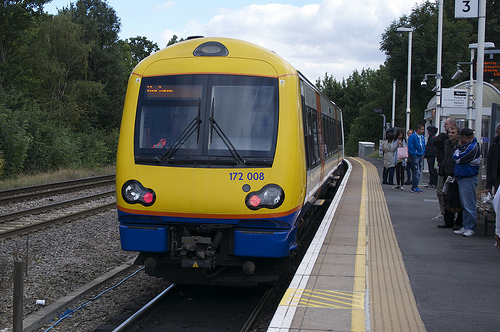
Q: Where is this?
A: This is at the station.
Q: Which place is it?
A: It is a station.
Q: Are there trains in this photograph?
A: Yes, there is a train.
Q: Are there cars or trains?
A: Yes, there is a train.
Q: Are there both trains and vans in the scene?
A: No, there is a train but no vans.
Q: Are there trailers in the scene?
A: No, there are no trailers.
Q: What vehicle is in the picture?
A: The vehicle is a train.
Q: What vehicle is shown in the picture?
A: The vehicle is a train.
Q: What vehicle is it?
A: The vehicle is a train.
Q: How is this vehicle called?
A: This is a train.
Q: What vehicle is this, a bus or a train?
A: This is a train.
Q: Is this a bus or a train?
A: This is a train.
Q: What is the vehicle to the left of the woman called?
A: The vehicle is a train.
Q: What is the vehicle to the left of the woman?
A: The vehicle is a train.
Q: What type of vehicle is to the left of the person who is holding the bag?
A: The vehicle is a train.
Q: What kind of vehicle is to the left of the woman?
A: The vehicle is a train.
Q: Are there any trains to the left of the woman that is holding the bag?
A: Yes, there is a train to the left of the woman.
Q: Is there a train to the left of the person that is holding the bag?
A: Yes, there is a train to the left of the woman.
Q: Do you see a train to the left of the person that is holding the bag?
A: Yes, there is a train to the left of the woman.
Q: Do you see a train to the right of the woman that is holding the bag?
A: No, the train is to the left of the woman.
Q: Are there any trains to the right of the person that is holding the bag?
A: No, the train is to the left of the woman.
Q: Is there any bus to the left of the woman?
A: No, there is a train to the left of the woman.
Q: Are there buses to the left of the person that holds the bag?
A: No, there is a train to the left of the woman.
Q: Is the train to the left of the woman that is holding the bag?
A: Yes, the train is to the left of the woman.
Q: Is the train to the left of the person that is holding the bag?
A: Yes, the train is to the left of the woman.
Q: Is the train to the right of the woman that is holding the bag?
A: No, the train is to the left of the woman.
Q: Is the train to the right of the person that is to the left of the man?
A: No, the train is to the left of the woman.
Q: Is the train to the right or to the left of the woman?
A: The train is to the left of the woman.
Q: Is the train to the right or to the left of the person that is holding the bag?
A: The train is to the left of the woman.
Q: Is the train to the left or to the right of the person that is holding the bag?
A: The train is to the left of the woman.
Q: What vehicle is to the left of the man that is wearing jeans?
A: The vehicle is a train.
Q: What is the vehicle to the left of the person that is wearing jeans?
A: The vehicle is a train.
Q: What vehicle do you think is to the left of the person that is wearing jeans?
A: The vehicle is a train.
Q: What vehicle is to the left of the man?
A: The vehicle is a train.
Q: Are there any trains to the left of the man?
A: Yes, there is a train to the left of the man.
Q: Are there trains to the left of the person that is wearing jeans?
A: Yes, there is a train to the left of the man.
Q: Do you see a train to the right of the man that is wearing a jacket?
A: No, the train is to the left of the man.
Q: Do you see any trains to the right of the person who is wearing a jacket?
A: No, the train is to the left of the man.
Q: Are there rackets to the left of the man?
A: No, there is a train to the left of the man.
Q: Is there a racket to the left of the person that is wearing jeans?
A: No, there is a train to the left of the man.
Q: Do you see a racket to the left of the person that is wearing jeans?
A: No, there is a train to the left of the man.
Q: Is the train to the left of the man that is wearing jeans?
A: Yes, the train is to the left of the man.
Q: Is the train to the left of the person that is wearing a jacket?
A: Yes, the train is to the left of the man.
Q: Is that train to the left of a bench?
A: No, the train is to the left of the man.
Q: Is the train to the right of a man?
A: No, the train is to the left of a man.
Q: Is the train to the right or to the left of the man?
A: The train is to the left of the man.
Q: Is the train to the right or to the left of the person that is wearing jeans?
A: The train is to the left of the man.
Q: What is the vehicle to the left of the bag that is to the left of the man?
A: The vehicle is a train.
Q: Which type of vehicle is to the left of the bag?
A: The vehicle is a train.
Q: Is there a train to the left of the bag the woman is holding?
A: Yes, there is a train to the left of the bag.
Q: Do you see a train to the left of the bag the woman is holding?
A: Yes, there is a train to the left of the bag.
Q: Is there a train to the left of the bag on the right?
A: Yes, there is a train to the left of the bag.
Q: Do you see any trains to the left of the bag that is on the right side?
A: Yes, there is a train to the left of the bag.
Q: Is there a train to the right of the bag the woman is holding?
A: No, the train is to the left of the bag.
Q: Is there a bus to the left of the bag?
A: No, there is a train to the left of the bag.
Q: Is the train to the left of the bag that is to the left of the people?
A: Yes, the train is to the left of the bag.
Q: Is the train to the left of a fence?
A: No, the train is to the left of the bag.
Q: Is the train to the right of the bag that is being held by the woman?
A: No, the train is to the left of the bag.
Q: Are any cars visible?
A: No, there are no cars.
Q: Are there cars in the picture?
A: No, there are no cars.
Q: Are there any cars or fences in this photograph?
A: No, there are no cars or fences.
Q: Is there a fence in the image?
A: No, there are no fences.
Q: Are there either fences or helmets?
A: No, there are no fences or helmets.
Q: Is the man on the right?
A: Yes, the man is on the right of the image.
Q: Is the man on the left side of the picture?
A: No, the man is on the right of the image.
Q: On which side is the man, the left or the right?
A: The man is on the right of the image.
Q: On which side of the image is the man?
A: The man is on the right of the image.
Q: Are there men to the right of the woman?
A: Yes, there is a man to the right of the woman.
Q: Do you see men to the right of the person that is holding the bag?
A: Yes, there is a man to the right of the woman.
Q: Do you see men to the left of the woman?
A: No, the man is to the right of the woman.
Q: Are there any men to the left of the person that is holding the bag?
A: No, the man is to the right of the woman.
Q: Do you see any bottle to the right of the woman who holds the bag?
A: No, there is a man to the right of the woman.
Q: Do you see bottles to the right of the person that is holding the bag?
A: No, there is a man to the right of the woman.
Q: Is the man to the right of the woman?
A: Yes, the man is to the right of the woman.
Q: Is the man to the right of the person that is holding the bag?
A: Yes, the man is to the right of the woman.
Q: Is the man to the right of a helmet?
A: No, the man is to the right of the woman.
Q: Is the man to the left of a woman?
A: No, the man is to the right of a woman.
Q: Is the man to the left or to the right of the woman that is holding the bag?
A: The man is to the right of the woman.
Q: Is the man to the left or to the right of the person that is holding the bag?
A: The man is to the right of the woman.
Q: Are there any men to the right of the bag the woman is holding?
A: Yes, there is a man to the right of the bag.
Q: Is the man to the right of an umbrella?
A: No, the man is to the right of the bag.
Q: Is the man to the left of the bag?
A: No, the man is to the right of the bag.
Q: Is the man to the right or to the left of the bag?
A: The man is to the right of the bag.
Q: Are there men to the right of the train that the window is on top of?
A: Yes, there is a man to the right of the train.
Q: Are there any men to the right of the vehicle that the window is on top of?
A: Yes, there is a man to the right of the train.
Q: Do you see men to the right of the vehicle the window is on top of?
A: Yes, there is a man to the right of the train.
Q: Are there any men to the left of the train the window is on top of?
A: No, the man is to the right of the train.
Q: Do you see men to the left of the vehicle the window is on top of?
A: No, the man is to the right of the train.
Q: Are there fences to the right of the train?
A: No, there is a man to the right of the train.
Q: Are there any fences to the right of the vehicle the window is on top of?
A: No, there is a man to the right of the train.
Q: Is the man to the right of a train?
A: Yes, the man is to the right of a train.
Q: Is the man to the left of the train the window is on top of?
A: No, the man is to the right of the train.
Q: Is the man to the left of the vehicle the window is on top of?
A: No, the man is to the right of the train.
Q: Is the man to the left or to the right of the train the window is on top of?
A: The man is to the right of the train.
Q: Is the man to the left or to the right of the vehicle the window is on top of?
A: The man is to the right of the train.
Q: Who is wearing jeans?
A: The man is wearing jeans.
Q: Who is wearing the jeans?
A: The man is wearing jeans.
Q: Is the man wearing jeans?
A: Yes, the man is wearing jeans.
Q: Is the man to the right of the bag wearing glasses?
A: No, the man is wearing jeans.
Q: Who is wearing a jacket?
A: The man is wearing a jacket.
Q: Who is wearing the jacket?
A: The man is wearing a jacket.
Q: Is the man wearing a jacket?
A: Yes, the man is wearing a jacket.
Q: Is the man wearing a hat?
A: No, the man is wearing a jacket.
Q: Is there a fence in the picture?
A: No, there are no fences.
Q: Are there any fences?
A: No, there are no fences.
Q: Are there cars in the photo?
A: No, there are no cars.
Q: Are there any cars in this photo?
A: No, there are no cars.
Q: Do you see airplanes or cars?
A: No, there are no cars or airplanes.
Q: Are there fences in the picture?
A: No, there are no fences.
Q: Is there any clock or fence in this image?
A: No, there are no fences or clocks.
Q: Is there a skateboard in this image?
A: No, there are no skateboards.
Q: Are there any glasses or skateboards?
A: No, there are no skateboards or glasses.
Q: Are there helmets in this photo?
A: No, there are no helmets.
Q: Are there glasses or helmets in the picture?
A: No, there are no helmets or glasses.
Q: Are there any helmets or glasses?
A: No, there are no helmets or glasses.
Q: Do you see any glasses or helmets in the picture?
A: No, there are no helmets or glasses.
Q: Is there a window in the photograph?
A: Yes, there is a window.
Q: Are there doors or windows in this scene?
A: Yes, there is a window.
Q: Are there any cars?
A: No, there are no cars.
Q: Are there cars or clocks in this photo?
A: No, there are no cars or clocks.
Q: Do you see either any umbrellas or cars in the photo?
A: No, there are no cars or umbrellas.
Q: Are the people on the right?
A: Yes, the people are on the right of the image.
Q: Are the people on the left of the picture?
A: No, the people are on the right of the image.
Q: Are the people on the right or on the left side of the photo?
A: The people are on the right of the image.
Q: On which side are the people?
A: The people are on the right of the image.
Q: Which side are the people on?
A: The people are on the right of the image.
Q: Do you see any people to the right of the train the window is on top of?
A: Yes, there are people to the right of the train.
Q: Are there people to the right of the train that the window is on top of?
A: Yes, there are people to the right of the train.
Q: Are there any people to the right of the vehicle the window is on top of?
A: Yes, there are people to the right of the train.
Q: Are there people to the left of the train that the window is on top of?
A: No, the people are to the right of the train.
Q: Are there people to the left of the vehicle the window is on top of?
A: No, the people are to the right of the train.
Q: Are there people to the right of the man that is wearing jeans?
A: Yes, there are people to the right of the man.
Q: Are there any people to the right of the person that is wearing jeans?
A: Yes, there are people to the right of the man.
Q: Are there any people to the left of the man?
A: No, the people are to the right of the man.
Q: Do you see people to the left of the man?
A: No, the people are to the right of the man.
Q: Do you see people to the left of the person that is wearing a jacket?
A: No, the people are to the right of the man.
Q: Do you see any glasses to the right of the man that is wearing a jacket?
A: No, there are people to the right of the man.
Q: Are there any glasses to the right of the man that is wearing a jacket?
A: No, there are people to the right of the man.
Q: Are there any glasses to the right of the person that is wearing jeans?
A: No, there are people to the right of the man.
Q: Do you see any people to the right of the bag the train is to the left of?
A: Yes, there are people to the right of the bag.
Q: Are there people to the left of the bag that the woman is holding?
A: No, the people are to the right of the bag.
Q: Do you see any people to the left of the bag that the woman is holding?
A: No, the people are to the right of the bag.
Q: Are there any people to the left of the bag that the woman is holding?
A: No, the people are to the right of the bag.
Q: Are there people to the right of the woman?
A: Yes, there are people to the right of the woman.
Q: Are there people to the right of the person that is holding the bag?
A: Yes, there are people to the right of the woman.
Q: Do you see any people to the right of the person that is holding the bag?
A: Yes, there are people to the right of the woman.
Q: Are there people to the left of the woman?
A: No, the people are to the right of the woman.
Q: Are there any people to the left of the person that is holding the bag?
A: No, the people are to the right of the woman.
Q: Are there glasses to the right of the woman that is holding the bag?
A: No, there are people to the right of the woman.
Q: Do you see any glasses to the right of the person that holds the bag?
A: No, there are people to the right of the woman.